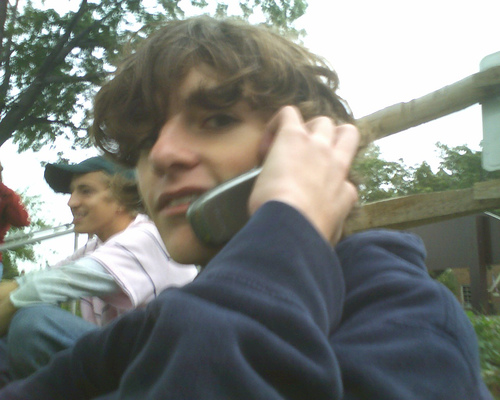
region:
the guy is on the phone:
[74, 95, 449, 379]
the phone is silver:
[194, 176, 259, 239]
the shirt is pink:
[101, 234, 182, 305]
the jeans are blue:
[21, 303, 87, 358]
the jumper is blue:
[42, 228, 461, 393]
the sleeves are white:
[14, 254, 118, 312]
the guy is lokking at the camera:
[76, 71, 470, 395]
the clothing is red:
[0, 188, 27, 226]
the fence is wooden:
[407, 78, 489, 210]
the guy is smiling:
[17, 176, 155, 304]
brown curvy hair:
[131, 40, 302, 64]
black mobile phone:
[195, 187, 245, 237]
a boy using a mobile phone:
[107, 72, 367, 287]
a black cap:
[46, 158, 131, 188]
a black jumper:
[116, 316, 463, 398]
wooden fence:
[396, 44, 496, 229]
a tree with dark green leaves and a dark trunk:
[11, 40, 72, 134]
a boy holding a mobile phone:
[186, 112, 385, 249]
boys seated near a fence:
[41, 18, 498, 398]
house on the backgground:
[431, 212, 475, 291]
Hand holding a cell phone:
[184, 105, 357, 250]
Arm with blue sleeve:
[111, 100, 363, 399]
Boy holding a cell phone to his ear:
[16, 13, 492, 398]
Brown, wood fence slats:
[339, 56, 498, 228]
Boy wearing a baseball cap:
[4, 150, 197, 382]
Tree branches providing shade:
[0, 0, 305, 153]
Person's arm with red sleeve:
[0, 163, 35, 270]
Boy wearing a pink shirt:
[8, 151, 205, 372]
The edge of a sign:
[477, 48, 499, 175]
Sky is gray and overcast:
[1, 0, 498, 275]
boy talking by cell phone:
[87, 9, 476, 399]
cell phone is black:
[184, 165, 267, 253]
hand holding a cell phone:
[181, 103, 373, 283]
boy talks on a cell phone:
[70, 5, 388, 317]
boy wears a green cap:
[6, 156, 202, 367]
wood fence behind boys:
[0, 14, 497, 399]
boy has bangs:
[56, 5, 402, 307]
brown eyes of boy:
[121, 105, 245, 154]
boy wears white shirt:
[0, 157, 195, 366]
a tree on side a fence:
[5, 3, 481, 399]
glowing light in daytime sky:
[301, 1, 497, 166]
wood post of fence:
[357, 65, 499, 145]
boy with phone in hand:
[90, 14, 361, 398]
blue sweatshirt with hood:
[1, 203, 486, 398]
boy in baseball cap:
[44, 153, 139, 235]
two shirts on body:
[0, 213, 199, 331]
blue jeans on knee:
[8, 301, 102, 372]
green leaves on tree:
[1, 51, 121, 151]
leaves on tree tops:
[355, 142, 497, 199]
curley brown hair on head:
[92, 13, 349, 168]